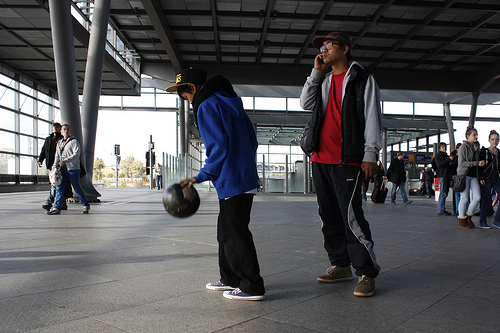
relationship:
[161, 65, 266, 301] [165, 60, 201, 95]
boy wearing hat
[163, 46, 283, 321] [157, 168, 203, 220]
boy bouncing a ball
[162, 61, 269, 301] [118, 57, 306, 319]
boy wearing jacket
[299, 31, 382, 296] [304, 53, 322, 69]
male holding cellphone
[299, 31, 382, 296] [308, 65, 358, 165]
male wearing t-shirt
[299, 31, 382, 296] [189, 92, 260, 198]
male wearing jacket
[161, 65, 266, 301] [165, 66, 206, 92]
boy wearing baseball cap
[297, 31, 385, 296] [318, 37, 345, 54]
boy wearing glasses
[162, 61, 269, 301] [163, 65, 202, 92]
boy wearing baseball cap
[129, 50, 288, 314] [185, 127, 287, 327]
boy wearing pants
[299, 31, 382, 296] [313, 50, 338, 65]
male using cell phone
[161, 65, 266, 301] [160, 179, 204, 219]
boy bouncing ball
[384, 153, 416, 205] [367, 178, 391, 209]
person pulling luggage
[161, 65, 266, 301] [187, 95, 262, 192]
boy wearing a jacket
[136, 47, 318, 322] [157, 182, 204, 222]
boy holding ball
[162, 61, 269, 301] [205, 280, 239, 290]
boy wearing shoe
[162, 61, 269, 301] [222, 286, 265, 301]
boy wearing shoes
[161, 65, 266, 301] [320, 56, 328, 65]
boy using a cell phone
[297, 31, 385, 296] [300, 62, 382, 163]
boy wearing a sweatshirt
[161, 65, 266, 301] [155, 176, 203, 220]
boy bouncing a ball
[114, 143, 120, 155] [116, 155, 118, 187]
sign on post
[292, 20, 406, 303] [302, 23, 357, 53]
male wearing hat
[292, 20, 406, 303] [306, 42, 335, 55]
male wearing glasses